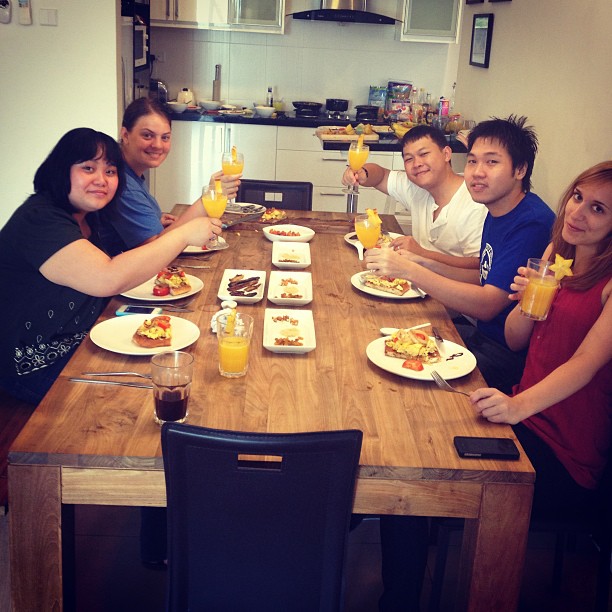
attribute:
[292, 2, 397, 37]
range hood — modernistic-shaped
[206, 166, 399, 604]
seats — empty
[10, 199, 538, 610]
dining table — natural wood